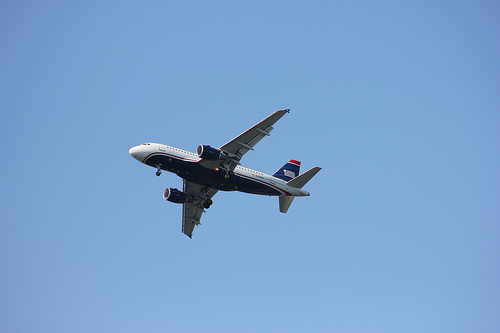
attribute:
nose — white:
[125, 145, 137, 161]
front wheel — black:
[154, 168, 164, 178]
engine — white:
[194, 140, 223, 160]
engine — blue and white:
[190, 142, 227, 166]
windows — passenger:
[163, 143, 194, 160]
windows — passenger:
[234, 165, 267, 180]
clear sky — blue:
[2, 0, 497, 331]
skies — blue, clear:
[2, 0, 499, 331]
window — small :
[162, 146, 176, 149]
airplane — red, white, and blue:
[125, 107, 322, 237]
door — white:
[268, 175, 280, 188]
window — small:
[147, 143, 151, 148]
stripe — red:
[284, 157, 302, 169]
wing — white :
[180, 177, 217, 237]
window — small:
[186, 150, 191, 155]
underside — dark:
[143, 155, 283, 197]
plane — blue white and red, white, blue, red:
[126, 108, 322, 240]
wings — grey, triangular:
[167, 109, 294, 236]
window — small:
[239, 162, 246, 174]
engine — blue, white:
[163, 185, 187, 200]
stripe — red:
[156, 153, 276, 194]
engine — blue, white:
[194, 141, 225, 162]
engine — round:
[195, 140, 235, 170]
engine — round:
[160, 185, 199, 206]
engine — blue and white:
[160, 183, 195, 206]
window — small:
[254, 168, 264, 175]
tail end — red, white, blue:
[274, 150, 326, 230]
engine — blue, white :
[195, 141, 220, 157]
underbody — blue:
[148, 152, 282, 197]